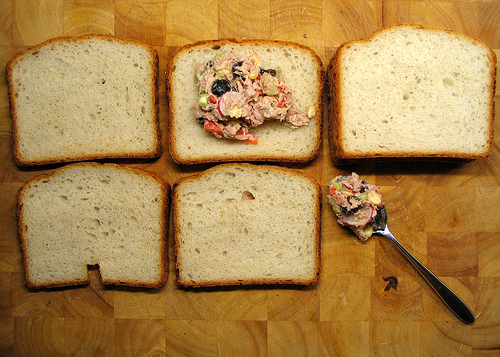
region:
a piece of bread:
[171, 50, 323, 162]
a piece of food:
[339, 29, 479, 152]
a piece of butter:
[172, 173, 350, 283]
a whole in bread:
[68, 248, 131, 317]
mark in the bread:
[228, 179, 283, 228]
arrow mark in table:
[379, 248, 411, 306]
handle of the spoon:
[386, 247, 497, 321]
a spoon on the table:
[322, 156, 494, 282]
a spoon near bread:
[316, 166, 498, 326]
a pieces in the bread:
[188, 50, 333, 172]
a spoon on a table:
[290, 109, 464, 266]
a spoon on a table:
[260, 145, 422, 296]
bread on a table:
[3, 36, 76, 116]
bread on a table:
[75, 17, 165, 116]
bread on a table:
[3, 158, 89, 230]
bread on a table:
[100, 155, 171, 225]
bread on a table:
[171, 160, 237, 239]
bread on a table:
[235, 165, 323, 240]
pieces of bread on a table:
[156, 24, 241, 126]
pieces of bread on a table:
[236, 32, 311, 117]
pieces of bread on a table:
[325, 21, 404, 126]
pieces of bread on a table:
[418, 28, 490, 118]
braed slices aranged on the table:
[48, 39, 498, 263]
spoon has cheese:
[337, 156, 470, 293]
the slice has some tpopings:
[203, 55, 302, 138]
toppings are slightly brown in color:
[205, 71, 296, 131]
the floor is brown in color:
[354, 286, 441, 353]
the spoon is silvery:
[384, 219, 469, 325]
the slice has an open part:
[61, 258, 152, 313]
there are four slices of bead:
[28, 1, 496, 326]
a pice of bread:
[158, 23, 399, 196]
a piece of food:
[160, 23, 372, 191]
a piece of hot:
[168, 55, 346, 182]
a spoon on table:
[318, 166, 458, 276]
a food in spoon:
[316, 173, 396, 244]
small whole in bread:
[86, 248, 110, 308]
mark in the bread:
[231, 179, 313, 237]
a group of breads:
[31, 33, 480, 314]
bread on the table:
[18, 25, 192, 157]